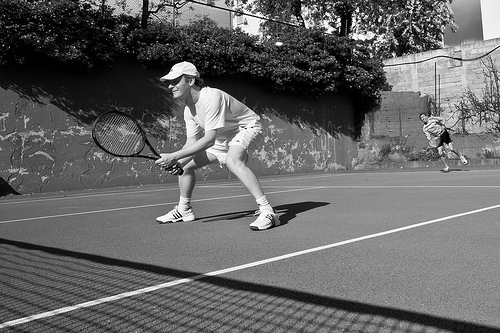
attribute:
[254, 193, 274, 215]
sock — White 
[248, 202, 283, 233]
shoe — black 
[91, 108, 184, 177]
tennis racket — black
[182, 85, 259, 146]
shirt — white 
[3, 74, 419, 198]
wall — long, peeling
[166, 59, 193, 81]
hat — white 